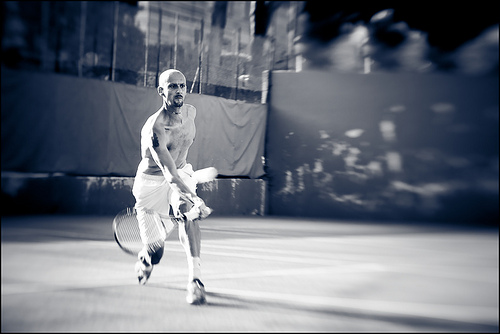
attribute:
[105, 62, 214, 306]
player — shirtless, male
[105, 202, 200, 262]
tennis racket — used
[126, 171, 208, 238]
shorts — white, whit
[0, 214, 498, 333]
tennis court — tennis court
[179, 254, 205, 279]
socks — socs, white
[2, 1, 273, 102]
fence — large, half covered, chain link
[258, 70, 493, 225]
wall — worn out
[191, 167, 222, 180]
tennis ball — struck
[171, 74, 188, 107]
expression — focused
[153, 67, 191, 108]
head — bald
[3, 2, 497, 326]
image — white, black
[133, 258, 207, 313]
sneakers — black, white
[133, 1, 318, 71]
buildings — tall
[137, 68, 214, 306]
man — bald, moving, playing